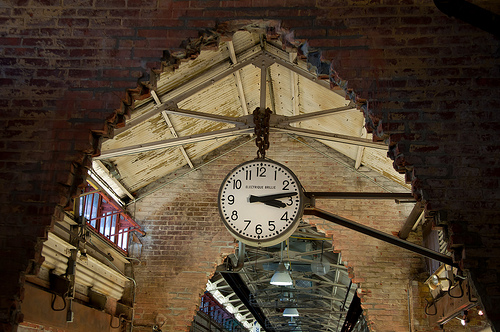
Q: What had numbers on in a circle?
A: A clock.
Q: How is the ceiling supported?
A: Metal beams.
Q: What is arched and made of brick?
A: The entrance.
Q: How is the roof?
A: Slanted.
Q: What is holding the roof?
A: Metal beans.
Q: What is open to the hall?
A: The passage way of the hallway.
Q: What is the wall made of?
A: Bricks.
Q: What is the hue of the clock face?
A: White.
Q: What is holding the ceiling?
A: Trusses.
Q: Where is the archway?
A: The entrance.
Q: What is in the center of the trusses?
A: A white clock.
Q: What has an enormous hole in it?
A: A brick wall.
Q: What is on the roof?
A: White metal rails.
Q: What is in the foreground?
A: Opening of a wall.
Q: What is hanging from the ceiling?
A: A clock.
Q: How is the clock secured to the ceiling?
A: A chain.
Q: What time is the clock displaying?
A: 3:13.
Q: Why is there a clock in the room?
A: To tell time.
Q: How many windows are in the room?
A: One window.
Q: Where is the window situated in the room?
A: On the left.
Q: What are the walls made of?
A: Brick walls.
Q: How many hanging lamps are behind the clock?
A: Two.